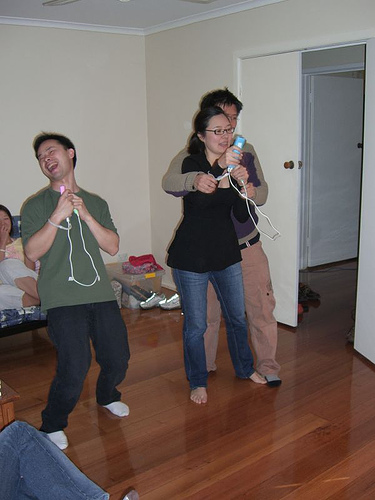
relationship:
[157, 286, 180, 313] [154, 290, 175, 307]
shoe has reflector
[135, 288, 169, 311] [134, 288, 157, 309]
shoe has reflector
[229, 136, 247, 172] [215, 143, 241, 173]
remote in hand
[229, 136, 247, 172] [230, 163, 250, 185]
remote in hand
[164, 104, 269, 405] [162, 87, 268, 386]
lady playing will game man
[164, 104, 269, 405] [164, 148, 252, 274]
lady wears black top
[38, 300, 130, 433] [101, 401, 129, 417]
pants over sock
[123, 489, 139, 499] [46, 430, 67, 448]
sock over sock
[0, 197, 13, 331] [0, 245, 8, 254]
girl with watch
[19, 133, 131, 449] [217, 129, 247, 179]
man holding controls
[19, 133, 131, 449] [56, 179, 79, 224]
man holding controls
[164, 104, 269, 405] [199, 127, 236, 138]
lady wearing eyeglasses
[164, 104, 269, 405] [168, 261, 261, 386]
lady in blue jeans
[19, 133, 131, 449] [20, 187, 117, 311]
man in t-shirt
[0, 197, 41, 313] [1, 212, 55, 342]
girl sitting on a couch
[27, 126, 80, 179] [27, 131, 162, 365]
head of a person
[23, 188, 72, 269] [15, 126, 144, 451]
arm of a person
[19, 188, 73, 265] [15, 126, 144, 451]
arm of a person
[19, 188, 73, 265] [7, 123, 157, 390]
arm of a person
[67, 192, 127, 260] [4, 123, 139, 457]
arm of a person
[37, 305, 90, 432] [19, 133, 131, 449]
leg of man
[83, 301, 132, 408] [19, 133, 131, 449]
leg of man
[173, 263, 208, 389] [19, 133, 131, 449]
leg of man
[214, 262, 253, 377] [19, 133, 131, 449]
leg of man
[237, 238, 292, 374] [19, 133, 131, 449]
leg of man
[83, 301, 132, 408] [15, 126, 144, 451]
leg of person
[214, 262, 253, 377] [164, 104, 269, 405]
leg of lady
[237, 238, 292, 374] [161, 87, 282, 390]
leg of man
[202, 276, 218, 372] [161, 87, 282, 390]
leg of man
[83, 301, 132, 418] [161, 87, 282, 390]
leg of man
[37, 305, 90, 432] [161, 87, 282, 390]
leg of man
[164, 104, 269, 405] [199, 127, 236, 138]
lady has eyeglasses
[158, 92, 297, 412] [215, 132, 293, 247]
two playing game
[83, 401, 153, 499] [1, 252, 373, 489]
shadow on floor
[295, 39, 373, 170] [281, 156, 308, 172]
open doorway with handle